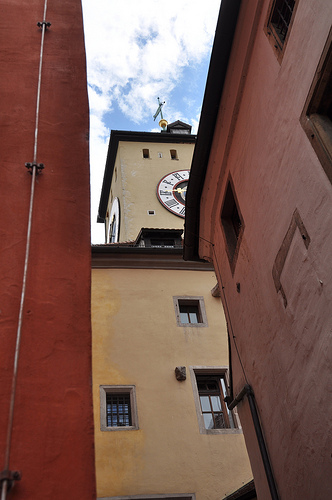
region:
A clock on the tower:
[158, 171, 184, 216]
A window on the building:
[106, 390, 130, 425]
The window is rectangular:
[196, 377, 227, 428]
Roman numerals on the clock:
[158, 170, 188, 214]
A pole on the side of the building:
[1, 0, 48, 498]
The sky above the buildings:
[82, 0, 227, 241]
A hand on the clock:
[165, 186, 186, 193]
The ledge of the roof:
[93, 244, 209, 270]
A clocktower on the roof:
[97, 129, 195, 240]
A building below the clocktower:
[180, 1, 330, 497]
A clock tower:
[97, 115, 208, 244]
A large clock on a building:
[153, 163, 191, 218]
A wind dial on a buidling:
[147, 92, 169, 131]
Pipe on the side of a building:
[222, 389, 280, 499]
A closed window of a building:
[100, 384, 139, 433]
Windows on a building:
[96, 286, 240, 438]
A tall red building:
[181, 1, 330, 495]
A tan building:
[90, 98, 258, 495]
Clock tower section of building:
[94, 91, 207, 239]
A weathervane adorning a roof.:
[152, 96, 167, 133]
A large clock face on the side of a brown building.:
[156, 171, 190, 217]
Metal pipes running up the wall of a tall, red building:
[0, 0, 49, 499]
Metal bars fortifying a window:
[106, 392, 133, 428]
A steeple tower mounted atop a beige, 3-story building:
[95, 120, 208, 244]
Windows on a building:
[100, 297, 237, 431]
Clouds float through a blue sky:
[81, 0, 219, 246]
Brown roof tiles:
[91, 229, 185, 247]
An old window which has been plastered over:
[271, 209, 322, 319]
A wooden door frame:
[298, 25, 330, 180]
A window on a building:
[168, 290, 212, 333]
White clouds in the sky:
[77, 0, 224, 245]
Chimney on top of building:
[159, 114, 193, 139]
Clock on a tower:
[154, 170, 187, 215]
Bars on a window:
[109, 397, 126, 423]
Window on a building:
[190, 366, 232, 432]